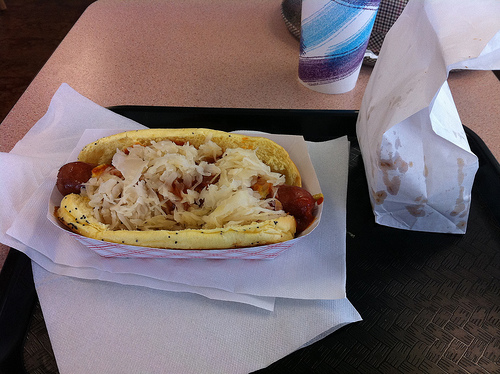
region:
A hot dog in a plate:
[37, 138, 345, 265]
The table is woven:
[357, 283, 494, 365]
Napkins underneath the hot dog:
[42, 221, 361, 367]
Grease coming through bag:
[365, 82, 495, 277]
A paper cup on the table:
[283, 0, 368, 107]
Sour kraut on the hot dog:
[105, 143, 272, 235]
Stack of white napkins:
[19, 219, 188, 369]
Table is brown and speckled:
[144, 30, 231, 101]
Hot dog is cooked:
[268, 166, 372, 264]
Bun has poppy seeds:
[57, 110, 404, 332]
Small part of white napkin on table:
[93, 345, 110, 359]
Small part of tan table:
[181, 45, 224, 82]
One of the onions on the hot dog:
[116, 157, 143, 180]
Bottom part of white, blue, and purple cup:
[298, 58, 358, 89]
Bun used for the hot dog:
[113, 232, 173, 247]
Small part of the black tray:
[374, 290, 400, 314]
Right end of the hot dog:
[283, 190, 313, 213]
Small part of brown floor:
[15, 20, 35, 48]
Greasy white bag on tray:
[363, 68, 469, 232]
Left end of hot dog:
[63, 162, 93, 189]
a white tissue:
[54, 73, 343, 368]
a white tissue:
[95, 138, 277, 360]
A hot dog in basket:
[13, 101, 372, 275]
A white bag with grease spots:
[324, 13, 483, 253]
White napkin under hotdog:
[11, 157, 438, 368]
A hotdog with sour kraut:
[47, 130, 322, 257]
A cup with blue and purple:
[293, 3, 378, 97]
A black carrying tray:
[21, 90, 498, 355]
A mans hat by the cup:
[278, 5, 472, 82]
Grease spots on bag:
[366, 137, 468, 231]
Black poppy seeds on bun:
[63, 195, 288, 249]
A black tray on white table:
[1, 90, 498, 372]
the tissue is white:
[118, 112, 321, 358]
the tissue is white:
[96, 97, 273, 259]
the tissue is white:
[39, 29, 355, 361]